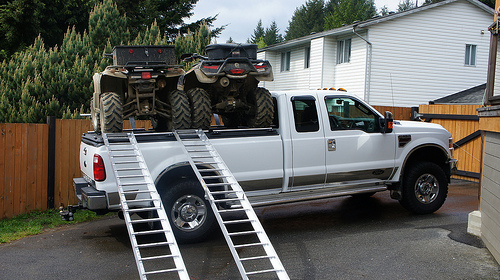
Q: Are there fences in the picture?
A: Yes, there is a fence.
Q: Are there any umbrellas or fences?
A: Yes, there is a fence.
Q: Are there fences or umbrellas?
A: Yes, there is a fence.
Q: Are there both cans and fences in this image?
A: No, there is a fence but no cans.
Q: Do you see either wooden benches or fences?
A: Yes, there is a wood fence.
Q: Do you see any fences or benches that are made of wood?
A: Yes, the fence is made of wood.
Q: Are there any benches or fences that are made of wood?
A: Yes, the fence is made of wood.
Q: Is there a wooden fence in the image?
A: Yes, there is a wood fence.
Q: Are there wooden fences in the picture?
A: Yes, there is a wood fence.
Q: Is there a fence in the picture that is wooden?
A: Yes, there is a fence that is wooden.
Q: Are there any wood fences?
A: Yes, there is a fence that is made of wood.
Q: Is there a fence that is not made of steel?
A: Yes, there is a fence that is made of wood.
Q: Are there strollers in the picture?
A: No, there are no strollers.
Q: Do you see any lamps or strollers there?
A: No, there are no strollers or lamps.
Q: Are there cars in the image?
A: No, there are no cars.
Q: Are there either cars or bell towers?
A: No, there are no cars or bell towers.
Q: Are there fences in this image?
A: Yes, there is a fence.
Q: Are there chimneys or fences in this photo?
A: Yes, there is a fence.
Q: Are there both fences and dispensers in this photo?
A: No, there is a fence but no dispensers.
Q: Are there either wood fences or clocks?
A: Yes, there is a wood fence.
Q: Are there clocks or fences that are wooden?
A: Yes, the fence is wooden.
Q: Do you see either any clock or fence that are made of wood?
A: Yes, the fence is made of wood.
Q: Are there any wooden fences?
A: Yes, there is a wood fence.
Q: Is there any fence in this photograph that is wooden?
A: Yes, there is a fence that is wooden.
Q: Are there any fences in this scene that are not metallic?
A: Yes, there is a wooden fence.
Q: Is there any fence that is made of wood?
A: Yes, there is a fence that is made of wood.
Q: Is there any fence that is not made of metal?
A: Yes, there is a fence that is made of wood.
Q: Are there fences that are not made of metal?
A: Yes, there is a fence that is made of wood.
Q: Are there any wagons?
A: No, there are no wagons.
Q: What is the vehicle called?
A: The vehicle is a trailer.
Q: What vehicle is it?
A: The vehicle is a trailer.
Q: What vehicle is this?
A: This is a trailer.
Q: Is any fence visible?
A: Yes, there is a fence.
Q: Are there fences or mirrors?
A: Yes, there is a fence.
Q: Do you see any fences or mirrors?
A: Yes, there is a fence.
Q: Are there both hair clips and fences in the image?
A: No, there is a fence but no hair clips.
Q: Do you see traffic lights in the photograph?
A: No, there are no traffic lights.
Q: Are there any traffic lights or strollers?
A: No, there are no traffic lights or strollers.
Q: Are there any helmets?
A: No, there are no helmets.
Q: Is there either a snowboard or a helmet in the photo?
A: No, there are no helmets or snowboards.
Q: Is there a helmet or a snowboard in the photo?
A: No, there are no helmets or snowboards.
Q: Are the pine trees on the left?
A: Yes, the pine trees are on the left of the image.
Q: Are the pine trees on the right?
A: No, the pine trees are on the left of the image.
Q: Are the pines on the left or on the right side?
A: The pines are on the left of the image.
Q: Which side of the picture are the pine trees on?
A: The pine trees are on the left of the image.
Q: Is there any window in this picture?
A: Yes, there is a window.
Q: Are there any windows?
A: Yes, there is a window.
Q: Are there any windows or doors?
A: Yes, there is a window.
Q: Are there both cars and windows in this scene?
A: No, there is a window but no cars.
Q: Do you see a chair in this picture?
A: No, there are no chairs.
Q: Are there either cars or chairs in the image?
A: No, there are no chairs or cars.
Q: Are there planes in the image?
A: No, there are no planes.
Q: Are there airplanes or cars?
A: No, there are no airplanes or cars.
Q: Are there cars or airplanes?
A: No, there are no airplanes or cars.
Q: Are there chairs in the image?
A: No, there are no chairs.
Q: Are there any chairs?
A: No, there are no chairs.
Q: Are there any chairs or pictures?
A: No, there are no chairs or pictures.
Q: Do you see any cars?
A: No, there are no cars.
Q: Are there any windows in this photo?
A: Yes, there is a window.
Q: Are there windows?
A: Yes, there is a window.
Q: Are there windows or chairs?
A: Yes, there is a window.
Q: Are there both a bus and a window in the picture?
A: No, there is a window but no buses.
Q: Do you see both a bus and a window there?
A: No, there is a window but no buses.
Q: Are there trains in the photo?
A: No, there are no trains.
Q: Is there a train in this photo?
A: No, there are no trains.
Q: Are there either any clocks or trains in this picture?
A: No, there are no trains or clocks.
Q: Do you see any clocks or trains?
A: No, there are no trains or clocks.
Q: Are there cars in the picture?
A: No, there are no cars.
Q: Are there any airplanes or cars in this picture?
A: No, there are no cars or airplanes.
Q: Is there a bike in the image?
A: No, there are no bikes.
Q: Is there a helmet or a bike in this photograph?
A: No, there are no bikes or helmets.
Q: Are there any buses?
A: No, there are no buses.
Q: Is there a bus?
A: No, there are no buses.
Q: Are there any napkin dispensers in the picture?
A: No, there are no napkin dispensers.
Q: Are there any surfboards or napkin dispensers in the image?
A: No, there are no napkin dispensers or surfboards.